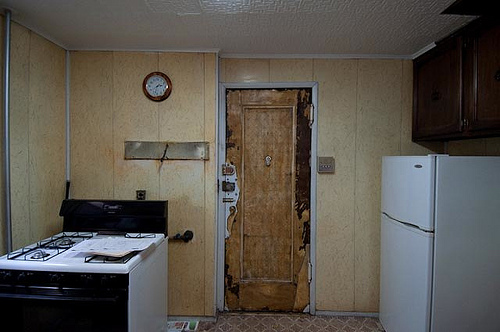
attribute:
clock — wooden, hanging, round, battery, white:
[116, 62, 195, 95]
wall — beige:
[116, 53, 247, 157]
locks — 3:
[205, 159, 238, 199]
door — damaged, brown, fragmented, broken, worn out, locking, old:
[216, 75, 352, 287]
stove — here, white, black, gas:
[48, 218, 137, 265]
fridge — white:
[385, 133, 489, 298]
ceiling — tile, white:
[107, 5, 310, 55]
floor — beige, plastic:
[216, 307, 296, 329]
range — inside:
[25, 240, 152, 318]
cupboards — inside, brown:
[389, 43, 474, 130]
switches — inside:
[303, 153, 331, 174]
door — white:
[372, 163, 404, 190]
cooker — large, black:
[39, 214, 203, 323]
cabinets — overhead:
[407, 45, 469, 148]